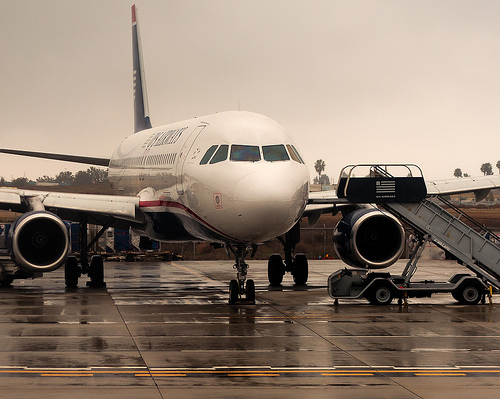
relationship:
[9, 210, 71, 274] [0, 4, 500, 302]
engine on airplane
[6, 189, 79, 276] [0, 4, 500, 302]
engine on airplane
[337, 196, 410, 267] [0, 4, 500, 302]
engine on airplane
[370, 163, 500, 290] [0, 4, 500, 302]
ramp leading to airplane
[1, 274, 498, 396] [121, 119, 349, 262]
ground under plane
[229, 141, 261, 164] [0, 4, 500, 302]
window on airplane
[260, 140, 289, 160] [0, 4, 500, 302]
window on airplane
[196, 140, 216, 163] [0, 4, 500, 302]
window on airplane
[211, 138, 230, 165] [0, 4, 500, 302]
window on airplane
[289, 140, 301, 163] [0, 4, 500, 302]
window on airplane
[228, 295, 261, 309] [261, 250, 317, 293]
blocks in front of wheel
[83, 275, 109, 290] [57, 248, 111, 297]
blocks in front of wheel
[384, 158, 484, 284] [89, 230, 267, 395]
ramp on platform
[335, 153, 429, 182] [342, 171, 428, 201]
railings over partition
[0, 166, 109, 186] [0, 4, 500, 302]
trees behind airplane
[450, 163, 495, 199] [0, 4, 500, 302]
tree behind airplane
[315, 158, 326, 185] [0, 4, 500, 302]
tree behind airplane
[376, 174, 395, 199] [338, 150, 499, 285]
logo on stairs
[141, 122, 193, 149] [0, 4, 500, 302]
logo on airplane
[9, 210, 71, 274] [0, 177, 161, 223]
engine on wing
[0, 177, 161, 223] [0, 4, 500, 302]
wing on airplane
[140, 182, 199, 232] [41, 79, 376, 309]
stripe on plane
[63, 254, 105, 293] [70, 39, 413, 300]
tires on plane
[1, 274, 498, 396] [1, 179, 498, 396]
ground on ground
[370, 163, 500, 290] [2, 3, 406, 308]
ramp on plane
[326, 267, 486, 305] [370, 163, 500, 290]
wheels on ramp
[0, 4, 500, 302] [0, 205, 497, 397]
airplane on ground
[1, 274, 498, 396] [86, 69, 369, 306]
ground under plane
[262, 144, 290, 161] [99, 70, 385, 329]
window on plane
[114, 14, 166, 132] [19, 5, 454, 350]
tail on plane